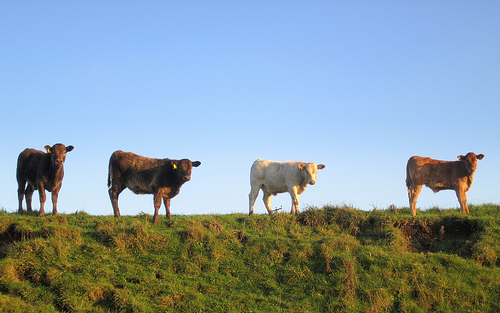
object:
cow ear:
[164, 159, 178, 170]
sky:
[0, 0, 499, 216]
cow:
[402, 151, 487, 218]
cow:
[248, 160, 325, 215]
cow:
[103, 149, 201, 223]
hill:
[0, 202, 498, 312]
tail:
[106, 160, 118, 188]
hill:
[12, 210, 474, 304]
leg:
[38, 181, 45, 216]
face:
[299, 162, 319, 185]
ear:
[314, 163, 325, 171]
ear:
[294, 161, 305, 172]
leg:
[16, 176, 27, 210]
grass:
[0, 203, 498, 312]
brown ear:
[43, 144, 52, 153]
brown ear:
[64, 145, 74, 153]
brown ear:
[190, 160, 201, 167]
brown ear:
[455, 154, 468, 161]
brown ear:
[473, 153, 483, 161]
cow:
[16, 143, 76, 218]